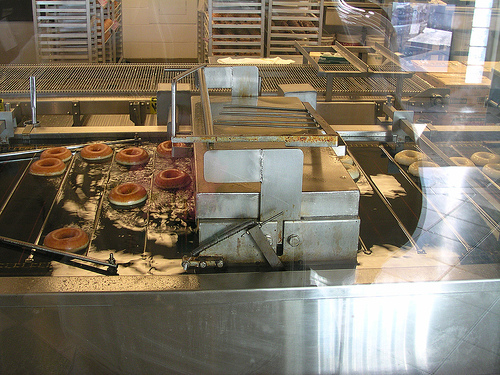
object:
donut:
[248, 218, 342, 299]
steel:
[394, 293, 426, 314]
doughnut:
[116, 159, 181, 231]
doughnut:
[45, 225, 91, 251]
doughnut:
[109, 178, 149, 206]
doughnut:
[155, 165, 193, 192]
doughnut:
[31, 159, 67, 176]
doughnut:
[82, 140, 114, 161]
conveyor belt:
[0, 61, 437, 97]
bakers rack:
[198, 1, 265, 62]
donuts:
[214, 27, 260, 35]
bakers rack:
[32, 0, 124, 64]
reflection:
[314, 166, 468, 374]